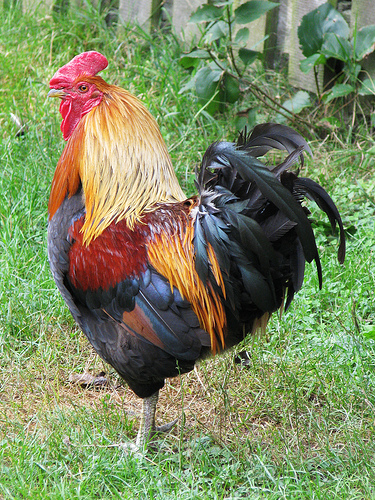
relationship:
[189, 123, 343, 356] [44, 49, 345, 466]
feather of rooster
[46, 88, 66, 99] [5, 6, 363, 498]
beak standing yard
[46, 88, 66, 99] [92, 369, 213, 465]
beak has feet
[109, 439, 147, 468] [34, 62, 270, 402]
foot on rooster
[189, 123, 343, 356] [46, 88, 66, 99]
feather on beak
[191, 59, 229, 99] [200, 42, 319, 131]
leaf growing on branch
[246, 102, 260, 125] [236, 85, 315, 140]
leaf growing on branch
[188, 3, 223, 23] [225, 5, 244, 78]
leaf growing on branch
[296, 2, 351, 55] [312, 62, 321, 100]
leaf growing on branch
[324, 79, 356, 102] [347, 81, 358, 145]
leaf growing on branch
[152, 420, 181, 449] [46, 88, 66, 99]
talon belonging to beak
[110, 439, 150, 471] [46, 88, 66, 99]
talon belonging to beak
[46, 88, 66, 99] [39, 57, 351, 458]
beak belonging to bird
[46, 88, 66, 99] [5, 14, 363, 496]
beak standing in field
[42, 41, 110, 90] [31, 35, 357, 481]
red crest growing on rooster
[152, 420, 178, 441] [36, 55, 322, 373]
foot steadying rooster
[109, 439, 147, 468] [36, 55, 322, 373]
foot steadying rooster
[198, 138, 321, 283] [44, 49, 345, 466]
feather adorning rooster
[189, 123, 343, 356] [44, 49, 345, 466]
feather adorning rooster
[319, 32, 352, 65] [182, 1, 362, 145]
leaf growing on plant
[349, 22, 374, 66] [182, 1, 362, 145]
leaf growing on plant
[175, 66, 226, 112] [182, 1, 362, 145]
leaf growing on plant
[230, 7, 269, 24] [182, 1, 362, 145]
leaf growing on plant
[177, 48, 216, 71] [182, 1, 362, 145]
leaf growing on plant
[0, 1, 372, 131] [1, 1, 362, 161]
fence standing in background